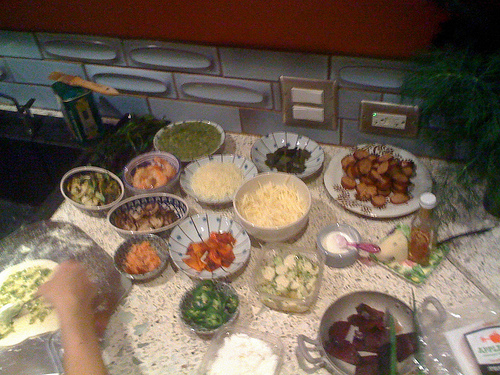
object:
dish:
[175, 281, 242, 336]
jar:
[406, 190, 447, 270]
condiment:
[407, 193, 438, 264]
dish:
[324, 141, 438, 215]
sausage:
[340, 146, 418, 209]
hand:
[40, 260, 104, 374]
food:
[2, 256, 61, 344]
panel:
[4, 34, 457, 150]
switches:
[279, 74, 340, 131]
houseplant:
[404, 38, 499, 219]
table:
[19, 114, 498, 373]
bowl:
[109, 193, 188, 235]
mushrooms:
[115, 203, 179, 232]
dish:
[315, 221, 365, 267]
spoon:
[346, 235, 381, 254]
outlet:
[357, 102, 423, 137]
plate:
[0, 217, 116, 365]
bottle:
[410, 209, 442, 271]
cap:
[417, 192, 437, 210]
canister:
[50, 79, 109, 143]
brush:
[47, 72, 121, 98]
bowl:
[315, 223, 362, 265]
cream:
[323, 233, 355, 254]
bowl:
[233, 171, 312, 240]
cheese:
[240, 176, 306, 224]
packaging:
[417, 303, 499, 373]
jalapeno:
[186, 276, 240, 327]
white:
[244, 178, 303, 224]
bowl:
[123, 151, 180, 194]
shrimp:
[129, 156, 174, 188]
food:
[328, 301, 414, 373]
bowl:
[298, 288, 447, 374]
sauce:
[159, 122, 220, 160]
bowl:
[154, 117, 225, 160]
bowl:
[116, 235, 170, 282]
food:
[123, 240, 161, 275]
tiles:
[6, 32, 464, 153]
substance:
[211, 330, 277, 374]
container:
[201, 325, 281, 374]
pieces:
[345, 147, 419, 206]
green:
[187, 279, 237, 327]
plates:
[361, 100, 420, 136]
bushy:
[403, 43, 500, 218]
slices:
[188, 290, 231, 328]